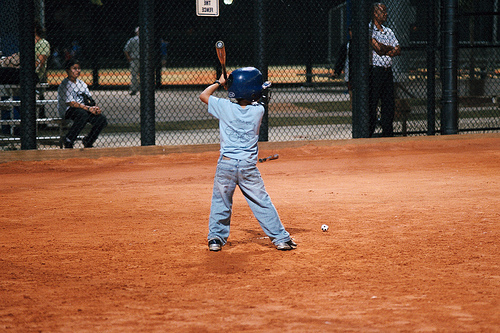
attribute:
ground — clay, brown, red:
[6, 160, 495, 329]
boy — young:
[197, 38, 301, 257]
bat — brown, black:
[214, 37, 237, 93]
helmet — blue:
[223, 66, 275, 106]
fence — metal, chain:
[3, 2, 494, 148]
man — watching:
[363, 3, 413, 136]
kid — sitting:
[53, 56, 115, 148]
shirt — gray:
[206, 96, 264, 163]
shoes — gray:
[209, 230, 300, 253]